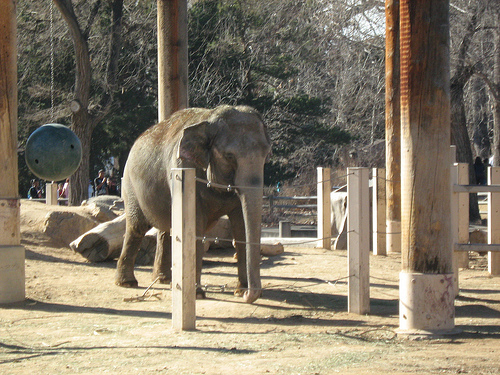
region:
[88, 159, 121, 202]
man holding a camera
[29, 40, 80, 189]
ball on a chain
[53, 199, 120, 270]
wood log behind the elephant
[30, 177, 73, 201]
people walking next to the exhibit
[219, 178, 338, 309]
rope between the poles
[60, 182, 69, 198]
woman carring a purse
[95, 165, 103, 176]
man is wearing a ballcap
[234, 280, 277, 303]
elephant's trunk is long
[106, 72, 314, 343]
elephant in an exhibit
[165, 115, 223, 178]
elephant has big flappy ears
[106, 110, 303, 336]
the elephant is in the zoo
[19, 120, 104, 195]
the ball is in the air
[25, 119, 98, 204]
the ball has holes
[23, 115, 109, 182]
the ball is hanging from the air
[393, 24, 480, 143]
the pole is rusty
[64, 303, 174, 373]
the sand is brwon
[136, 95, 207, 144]
a brown patch is on the elephant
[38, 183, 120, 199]
the people are spectating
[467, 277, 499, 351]
shadows are on the ground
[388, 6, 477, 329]
the pole is cemented to the ground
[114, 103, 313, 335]
grey elephant in pen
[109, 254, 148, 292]
leg of grey elephant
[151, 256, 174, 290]
leg of grey elephant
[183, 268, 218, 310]
leg of grey elephant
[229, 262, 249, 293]
leg of grey elephant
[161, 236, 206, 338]
fence post in enclosure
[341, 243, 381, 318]
fence post in enclosure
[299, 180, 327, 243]
fence post in enclosure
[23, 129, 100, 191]
ball hanging in pen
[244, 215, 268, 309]
trunk of grey elephant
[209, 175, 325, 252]
two ropes tied to posts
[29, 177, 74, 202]
people walking around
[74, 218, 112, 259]
large wood log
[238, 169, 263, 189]
spot on elephant's nose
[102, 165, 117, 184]
man holding a camera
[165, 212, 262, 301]
elephant standing in front of the ropes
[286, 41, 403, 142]
no leaves on the tree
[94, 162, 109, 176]
man is wearing a hat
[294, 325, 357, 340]
straw on the ground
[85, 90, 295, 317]
an elephant in a zoo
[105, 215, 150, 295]
an elephant's stubby leg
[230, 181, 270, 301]
an elephant's long trunk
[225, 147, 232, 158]
an elephant's eye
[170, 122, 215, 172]
an elephant's large ear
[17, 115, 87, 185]
an elephant's play toy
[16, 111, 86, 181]
a round black ball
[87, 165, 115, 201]
a man standing up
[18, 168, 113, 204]
several people watching an elephant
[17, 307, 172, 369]
very sandy soil